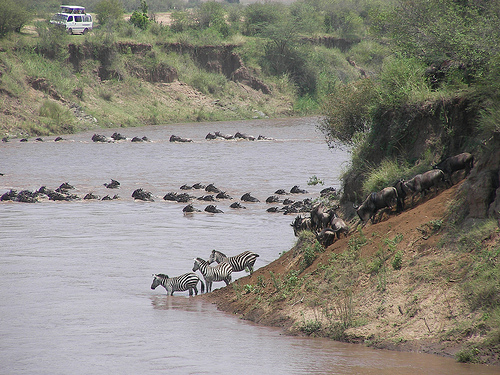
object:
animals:
[54, 136, 67, 141]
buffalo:
[205, 132, 216, 139]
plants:
[330, 259, 361, 329]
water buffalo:
[352, 186, 404, 225]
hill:
[192, 76, 500, 365]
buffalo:
[181, 201, 201, 212]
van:
[48, 12, 94, 35]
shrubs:
[375, 0, 497, 95]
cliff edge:
[338, 90, 499, 197]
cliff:
[0, 31, 393, 136]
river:
[0, 114, 498, 372]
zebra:
[149, 271, 204, 296]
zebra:
[192, 256, 234, 293]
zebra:
[208, 249, 260, 274]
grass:
[349, 242, 470, 299]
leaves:
[324, 66, 381, 106]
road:
[0, 6, 203, 32]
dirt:
[200, 176, 500, 368]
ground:
[208, 163, 496, 365]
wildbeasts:
[20, 137, 29, 142]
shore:
[205, 83, 498, 368]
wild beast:
[82, 189, 97, 199]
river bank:
[0, 38, 384, 137]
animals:
[59, 181, 75, 189]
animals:
[257, 134, 275, 140]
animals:
[131, 136, 144, 142]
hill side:
[193, 102, 499, 363]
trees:
[384, 7, 495, 89]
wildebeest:
[104, 178, 121, 189]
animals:
[179, 184, 193, 191]